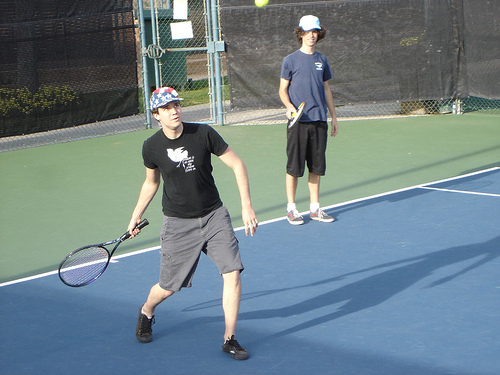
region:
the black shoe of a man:
[134, 307, 157, 343]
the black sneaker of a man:
[222, 333, 250, 361]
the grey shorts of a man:
[157, 211, 245, 288]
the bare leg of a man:
[140, 276, 172, 317]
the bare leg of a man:
[218, 260, 240, 340]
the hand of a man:
[240, 208, 257, 233]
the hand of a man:
[125, 218, 139, 236]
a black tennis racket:
[57, 220, 151, 289]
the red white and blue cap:
[149, 86, 180, 111]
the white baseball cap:
[300, 14, 322, 32]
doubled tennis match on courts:
[53, 8, 405, 360]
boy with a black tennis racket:
[43, 77, 272, 358]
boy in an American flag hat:
[138, 79, 190, 136]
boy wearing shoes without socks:
[127, 300, 269, 365]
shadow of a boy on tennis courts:
[267, 236, 495, 341]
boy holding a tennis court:
[273, 12, 377, 233]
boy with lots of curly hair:
[292, 5, 332, 49]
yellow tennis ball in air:
[248, 0, 282, 14]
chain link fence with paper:
[143, 2, 233, 82]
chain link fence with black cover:
[11, 14, 112, 106]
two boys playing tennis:
[51, 8, 377, 361]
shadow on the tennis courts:
[251, 232, 489, 341]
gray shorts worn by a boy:
[153, 209, 246, 291]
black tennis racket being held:
[53, 219, 160, 301]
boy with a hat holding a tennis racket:
[266, 7, 363, 232]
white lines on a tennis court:
[379, 152, 474, 222]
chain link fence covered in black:
[371, 23, 483, 99]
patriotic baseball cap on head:
[137, 80, 192, 107]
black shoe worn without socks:
[208, 333, 267, 365]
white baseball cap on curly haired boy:
[290, 9, 330, 34]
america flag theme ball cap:
[149, 84, 181, 109]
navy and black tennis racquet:
[46, 214, 154, 291]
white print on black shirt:
[164, 142, 201, 179]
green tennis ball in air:
[252, 1, 268, 8]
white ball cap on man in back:
[296, 12, 323, 35]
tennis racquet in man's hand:
[284, 101, 306, 128]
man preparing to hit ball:
[55, 82, 263, 365]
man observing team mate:
[277, 11, 342, 231]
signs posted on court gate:
[162, 0, 197, 42]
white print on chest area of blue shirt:
[311, 58, 323, 74]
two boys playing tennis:
[47, 10, 432, 367]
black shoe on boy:
[116, 300, 164, 347]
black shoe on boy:
[203, 333, 254, 356]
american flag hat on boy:
[135, 88, 188, 108]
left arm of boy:
[221, 169, 263, 244]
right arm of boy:
[119, 177, 163, 248]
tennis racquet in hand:
[64, 238, 134, 290]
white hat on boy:
[286, 15, 321, 33]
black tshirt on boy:
[132, 124, 235, 220]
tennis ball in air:
[250, 0, 272, 20]